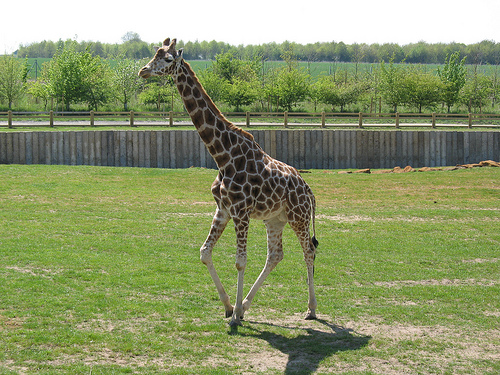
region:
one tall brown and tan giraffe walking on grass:
[137, 31, 351, 348]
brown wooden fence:
[8, 111, 498, 189]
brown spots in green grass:
[56, 271, 451, 370]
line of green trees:
[14, 49, 491, 114]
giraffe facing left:
[139, 39, 344, 342]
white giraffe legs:
[199, 225, 325, 325]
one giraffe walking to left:
[137, 39, 333, 344]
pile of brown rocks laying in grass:
[354, 154, 499, 179]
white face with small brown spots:
[134, 34, 205, 96]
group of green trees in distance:
[21, 34, 489, 61]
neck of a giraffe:
[167, 85, 227, 122]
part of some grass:
[90, 242, 138, 284]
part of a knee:
[232, 255, 255, 266]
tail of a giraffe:
[305, 223, 322, 260]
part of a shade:
[273, 345, 293, 372]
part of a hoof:
[216, 305, 234, 329]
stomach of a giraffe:
[246, 168, 281, 210]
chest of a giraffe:
[204, 169, 244, 214]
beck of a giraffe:
[208, 121, 243, 178]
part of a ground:
[338, 277, 391, 339]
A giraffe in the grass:
[104, 36, 384, 351]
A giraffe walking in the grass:
[104, 39, 355, 343]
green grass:
[42, 188, 183, 320]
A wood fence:
[24, 91, 160, 216]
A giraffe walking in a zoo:
[63, 39, 352, 339]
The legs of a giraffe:
[169, 200, 347, 340]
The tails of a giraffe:
[289, 167, 336, 271]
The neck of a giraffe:
[166, 67, 237, 171]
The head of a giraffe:
[125, 40, 196, 110]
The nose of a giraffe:
[134, 60, 165, 91]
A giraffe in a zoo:
[114, 36, 372, 352]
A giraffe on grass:
[104, 25, 354, 357]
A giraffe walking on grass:
[122, 31, 367, 347]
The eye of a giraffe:
[154, 50, 177, 71]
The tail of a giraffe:
[291, 154, 327, 266]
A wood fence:
[267, 115, 468, 182]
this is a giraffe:
[147, 40, 334, 302]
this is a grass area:
[62, 215, 142, 285]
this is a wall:
[316, 130, 438, 161]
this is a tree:
[57, 55, 107, 101]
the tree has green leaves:
[61, 70, 68, 80]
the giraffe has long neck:
[171, 62, 231, 145]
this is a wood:
[119, 131, 126, 166]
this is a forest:
[27, 41, 147, 58]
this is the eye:
[163, 53, 174, 62]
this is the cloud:
[191, 15, 288, 40]